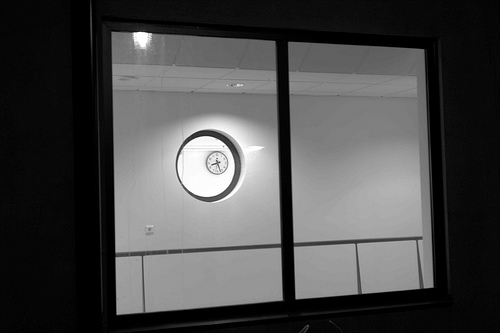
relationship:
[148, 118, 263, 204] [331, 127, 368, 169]
clock on wall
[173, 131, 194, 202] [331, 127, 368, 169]
window on wall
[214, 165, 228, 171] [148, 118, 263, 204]
hands on clock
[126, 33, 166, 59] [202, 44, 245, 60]
light on ceiling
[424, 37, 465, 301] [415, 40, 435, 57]
side of window seal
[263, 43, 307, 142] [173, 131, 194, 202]
middle of window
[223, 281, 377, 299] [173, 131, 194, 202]
bottom of window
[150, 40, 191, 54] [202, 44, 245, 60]
glare on ceiling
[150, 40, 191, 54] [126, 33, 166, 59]
glare from light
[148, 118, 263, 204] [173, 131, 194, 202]
clock seen through window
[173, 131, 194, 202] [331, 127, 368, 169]
window in wall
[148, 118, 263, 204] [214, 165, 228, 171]
clock has hands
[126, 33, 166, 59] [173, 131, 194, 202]
light shining at top of window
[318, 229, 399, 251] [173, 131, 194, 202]
railing outside window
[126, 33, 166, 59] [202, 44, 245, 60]
light in ceiling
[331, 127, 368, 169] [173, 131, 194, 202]
wall outside window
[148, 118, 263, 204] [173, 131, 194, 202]
clock outside window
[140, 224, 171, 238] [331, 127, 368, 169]
light switch on wall